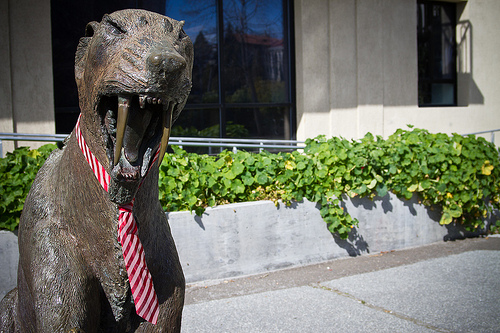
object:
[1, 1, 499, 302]
building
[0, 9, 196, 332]
sculpture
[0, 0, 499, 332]
scene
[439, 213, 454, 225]
leaves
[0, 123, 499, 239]
plants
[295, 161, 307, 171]
leaves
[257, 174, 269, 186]
leaves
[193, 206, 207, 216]
leaves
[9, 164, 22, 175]
leaves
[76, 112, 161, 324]
tie